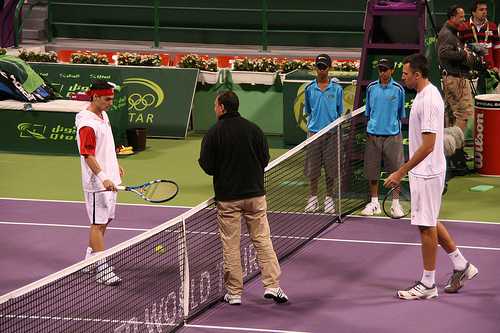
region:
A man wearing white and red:
[72, 78, 179, 285]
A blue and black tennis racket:
[109, 180, 179, 202]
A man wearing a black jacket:
[198, 90, 288, 305]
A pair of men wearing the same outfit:
[304, 55, 405, 215]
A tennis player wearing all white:
[382, 54, 487, 299]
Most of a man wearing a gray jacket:
[435, 6, 476, 173]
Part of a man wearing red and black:
[457, 0, 499, 74]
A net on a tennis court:
[1, 104, 375, 331]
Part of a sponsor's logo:
[15, 117, 79, 144]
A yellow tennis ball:
[152, 241, 163, 254]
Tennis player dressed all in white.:
[377, 54, 484, 301]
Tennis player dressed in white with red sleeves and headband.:
[72, 79, 127, 286]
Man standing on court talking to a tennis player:
[183, 84, 299, 310]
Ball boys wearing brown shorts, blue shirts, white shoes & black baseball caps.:
[292, 51, 406, 223]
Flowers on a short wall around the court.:
[2, 41, 363, 73]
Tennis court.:
[0, 195, 499, 332]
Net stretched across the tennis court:
[4, 103, 367, 331]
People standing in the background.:
[437, 3, 499, 169]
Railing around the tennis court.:
[2, 1, 499, 56]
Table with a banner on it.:
[0, 98, 134, 155]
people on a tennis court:
[73, 50, 478, 301]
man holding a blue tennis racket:
[102, 176, 179, 203]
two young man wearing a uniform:
[307, 78, 407, 179]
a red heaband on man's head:
[85, 88, 114, 99]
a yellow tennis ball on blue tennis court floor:
[153, 243, 167, 255]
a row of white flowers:
[18, 47, 361, 83]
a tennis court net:
[3, 98, 390, 332]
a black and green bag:
[476, 64, 495, 96]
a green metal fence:
[46, 5, 446, 52]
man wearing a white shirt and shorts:
[408, 83, 448, 225]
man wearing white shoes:
[385, 59, 476, 304]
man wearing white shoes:
[197, 92, 290, 307]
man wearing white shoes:
[76, 86, 133, 286]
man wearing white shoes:
[362, 55, 404, 218]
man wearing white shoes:
[298, 55, 345, 212]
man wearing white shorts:
[395, 57, 479, 297]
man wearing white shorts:
[75, 79, 142, 284]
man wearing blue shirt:
[362, 60, 405, 218]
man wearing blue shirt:
[300, 53, 347, 210]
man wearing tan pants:
[195, 92, 295, 308]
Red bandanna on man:
[80, 87, 116, 100]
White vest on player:
[68, 108, 130, 195]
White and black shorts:
[72, 182, 124, 232]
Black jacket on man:
[197, 113, 278, 200]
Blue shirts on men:
[302, 77, 409, 140]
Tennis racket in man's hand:
[105, 169, 187, 212]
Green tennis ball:
[150, 242, 170, 257]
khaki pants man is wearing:
[212, 193, 283, 298]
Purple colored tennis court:
[0, 194, 499, 331]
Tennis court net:
[0, 102, 385, 331]